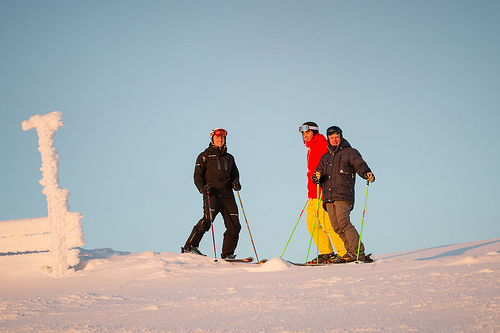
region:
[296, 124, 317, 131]
White snow goggles on the skier's head.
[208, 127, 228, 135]
The red ski goggles on the skier's head.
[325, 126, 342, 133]
The black goggles on the skier's head.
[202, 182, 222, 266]
Left ski pole held by the skier on the left.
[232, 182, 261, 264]
Right ski pole of the skier on the left.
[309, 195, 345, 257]
Yellow ski pants worn by the skier in the middle.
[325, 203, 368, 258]
Brown ski pants worn by the skier on the right.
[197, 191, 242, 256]
Black pants worn by the skier on the left.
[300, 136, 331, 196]
Red coat worn by the skier in the middle.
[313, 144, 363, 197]
Black ski coat worn by the skier in brown pants.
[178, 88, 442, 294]
men posing for a picture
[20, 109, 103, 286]
an ic e sculpture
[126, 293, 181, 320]
tracks in the snow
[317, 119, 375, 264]
a man holding green ski poles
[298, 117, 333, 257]
a man wearing yellow points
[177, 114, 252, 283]
a man wearing a black snowsuit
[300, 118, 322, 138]
snow goggles on a head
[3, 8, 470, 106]
a clear blue sky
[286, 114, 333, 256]
a skier in a red jacket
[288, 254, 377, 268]
ski attached to their feet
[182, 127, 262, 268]
A person in a black suit.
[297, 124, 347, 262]
A person in a red suit.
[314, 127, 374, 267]
A person skiing.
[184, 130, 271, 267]
A person skiing.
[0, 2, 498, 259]
The bright blue sky.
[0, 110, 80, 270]
A white structure made of snow.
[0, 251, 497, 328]
The snowy landscape.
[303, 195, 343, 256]
The man's yellow pants.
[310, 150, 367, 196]
A black jacket.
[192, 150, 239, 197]
A black jacket.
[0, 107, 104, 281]
object covered in snow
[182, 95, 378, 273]
three skiers standing in the snow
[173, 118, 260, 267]
skier wearing a black outfit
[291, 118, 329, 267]
skier with a red jacket and orange pants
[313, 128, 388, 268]
skier wearing a brown outfit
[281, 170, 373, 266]
bright green with red sky poles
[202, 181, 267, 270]
red sky poles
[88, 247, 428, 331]
snow covered ground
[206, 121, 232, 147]
goggles on forehead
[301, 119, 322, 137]
goggles with a white band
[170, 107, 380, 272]
People are skiing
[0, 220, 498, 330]
The snow is white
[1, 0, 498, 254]
Ski is clear and blue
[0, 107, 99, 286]
Snow formed up something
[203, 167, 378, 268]
Everyone is holding ski poles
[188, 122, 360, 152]
Every person has on ski goggles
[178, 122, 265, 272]
This person is wearing black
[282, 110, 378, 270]
Guy in the back is wearing Orange and red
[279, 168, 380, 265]
Ski poles are neon colors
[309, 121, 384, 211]
Person is wearing grey coat